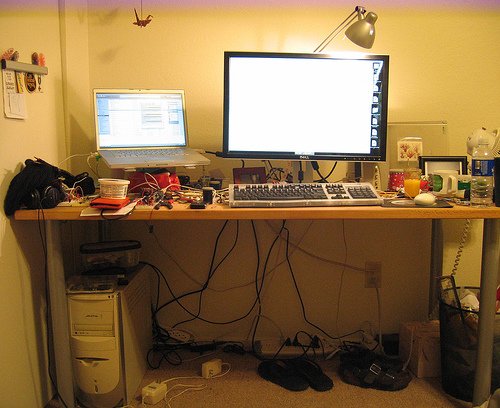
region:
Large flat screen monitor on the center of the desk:
[218, 48, 390, 165]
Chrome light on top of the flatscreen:
[310, 3, 380, 55]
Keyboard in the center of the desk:
[225, 178, 387, 210]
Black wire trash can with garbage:
[428, 271, 488, 406]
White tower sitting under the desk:
[63, 256, 156, 406]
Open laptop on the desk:
[90, 84, 212, 174]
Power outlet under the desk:
[358, 256, 385, 296]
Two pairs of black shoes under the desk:
[250, 341, 418, 395]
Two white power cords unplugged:
[133, 353, 229, 406]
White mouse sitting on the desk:
[410, 188, 440, 210]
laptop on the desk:
[88, 89, 198, 168]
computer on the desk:
[212, 47, 389, 209]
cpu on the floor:
[68, 265, 158, 405]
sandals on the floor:
[352, 353, 397, 389]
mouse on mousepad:
[412, 189, 436, 203]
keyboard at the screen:
[238, 180, 375, 208]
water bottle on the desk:
[472, 140, 494, 207]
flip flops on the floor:
[250, 345, 335, 399]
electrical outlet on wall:
[358, 263, 380, 295]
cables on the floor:
[98, 360, 220, 395]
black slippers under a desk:
[251, 350, 335, 396]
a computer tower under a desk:
[66, 275, 139, 405]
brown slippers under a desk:
[335, 351, 411, 393]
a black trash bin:
[428, 282, 497, 399]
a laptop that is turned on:
[91, 84, 209, 170]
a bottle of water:
[472, 138, 494, 205]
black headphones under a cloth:
[23, 187, 59, 212]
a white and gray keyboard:
[226, 179, 381, 208]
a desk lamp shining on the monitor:
[267, 5, 382, 62]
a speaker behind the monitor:
[358, 148, 394, 198]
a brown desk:
[12, 176, 499, 406]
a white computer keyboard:
[223, 178, 381, 206]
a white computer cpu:
[66, 265, 156, 407]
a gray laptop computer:
[90, 84, 210, 169]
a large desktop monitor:
[225, 45, 393, 161]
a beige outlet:
[365, 258, 385, 288]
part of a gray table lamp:
[308, 1, 383, 51]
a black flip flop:
[250, 355, 310, 393]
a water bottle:
[468, 136, 494, 206]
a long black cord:
[281, 230, 358, 349]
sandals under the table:
[245, 339, 423, 406]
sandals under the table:
[176, 175, 436, 405]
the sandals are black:
[239, 310, 391, 403]